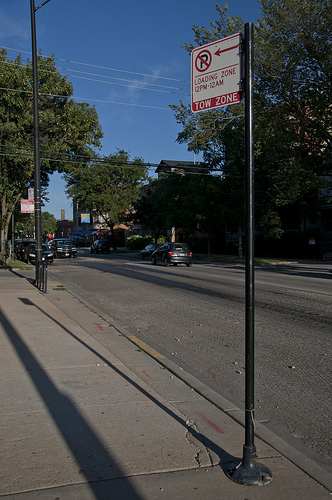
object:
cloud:
[103, 62, 168, 110]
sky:
[0, 0, 262, 184]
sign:
[191, 32, 241, 114]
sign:
[20, 199, 35, 214]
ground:
[0, 241, 332, 500]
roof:
[155, 158, 208, 172]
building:
[154, 158, 215, 187]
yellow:
[128, 333, 166, 360]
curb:
[48, 268, 332, 492]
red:
[190, 32, 241, 112]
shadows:
[15, 293, 244, 475]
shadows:
[254, 268, 332, 281]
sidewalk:
[191, 245, 332, 265]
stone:
[288, 365, 296, 369]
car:
[150, 241, 193, 267]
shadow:
[0, 310, 144, 500]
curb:
[273, 253, 332, 275]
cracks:
[185, 424, 201, 468]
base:
[224, 456, 274, 486]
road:
[41, 245, 332, 469]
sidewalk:
[0, 257, 332, 500]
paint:
[193, 408, 225, 434]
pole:
[238, 21, 259, 474]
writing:
[130, 329, 165, 359]